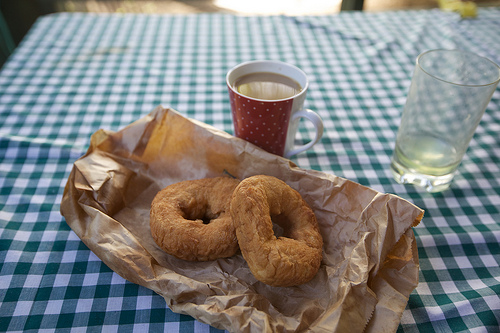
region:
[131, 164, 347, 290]
Two donuts on a paper bag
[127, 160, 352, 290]
Two donuts next to each other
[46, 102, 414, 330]
A paper bag with two donuts on it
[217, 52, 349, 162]
A cup of coffee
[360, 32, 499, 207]
A drinking glass that is almost empty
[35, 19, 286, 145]
A checkered table cloth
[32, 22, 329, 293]
A green and white table cloth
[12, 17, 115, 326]
A green and white checkered tablecloth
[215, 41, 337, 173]
A red and white coffee cup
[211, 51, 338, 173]
A cup full of coffee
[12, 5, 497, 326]
Checkered table cloth covering the table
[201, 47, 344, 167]
Red and white coffee mug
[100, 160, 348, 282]
Two round donuts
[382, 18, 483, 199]
Nearly empty glass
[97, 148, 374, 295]
Donuts on a paper bag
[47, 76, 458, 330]
Paper bag on the table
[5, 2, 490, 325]
Green and white table cloth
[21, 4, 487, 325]
Nobody shown in the photo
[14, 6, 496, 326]
Photo taken in the morning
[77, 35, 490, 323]
Breakfast time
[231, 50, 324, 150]
Cup of Coffe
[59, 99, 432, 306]
Paper bag on a table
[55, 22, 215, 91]
Table with plaid cloth on it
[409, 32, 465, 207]
Tall glass with water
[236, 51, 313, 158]
Red and White coffee mug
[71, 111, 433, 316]
Brown paper bag on a plaid table cloth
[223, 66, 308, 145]
Mug with hot coffee in it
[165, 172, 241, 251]
Brown plain donut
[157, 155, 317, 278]
Donuts side by side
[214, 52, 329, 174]
The cup is full.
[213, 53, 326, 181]
The cup is red and white.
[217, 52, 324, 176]
Cup has polka dots.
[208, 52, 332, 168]
Coffe with cream in a cup.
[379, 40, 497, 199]
The glass is clear.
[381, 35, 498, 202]
The glass is breakable.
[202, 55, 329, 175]
The cup has a handle.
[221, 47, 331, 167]
The cup is breakable.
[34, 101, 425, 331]
The bag is brown.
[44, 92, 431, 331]
The bag is wrinkled.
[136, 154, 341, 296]
two donuts on a bag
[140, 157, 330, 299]
two donuts with holes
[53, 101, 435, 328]
a brown paper bag under a donut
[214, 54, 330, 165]
cap of coffee on a table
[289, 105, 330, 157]
handle of cup is white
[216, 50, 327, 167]
cup is white and red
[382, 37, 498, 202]
glass with liquid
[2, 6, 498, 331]
table cloth is color green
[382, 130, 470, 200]
little liquid in a glass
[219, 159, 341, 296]
a donut over other donut